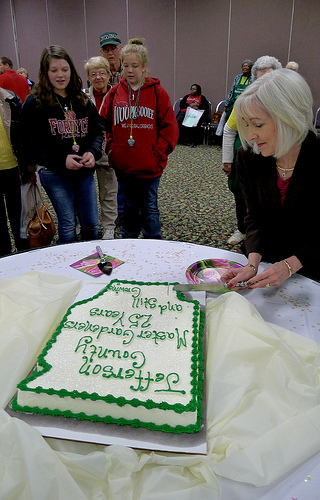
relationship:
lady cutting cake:
[217, 68, 319, 291] [6, 278, 204, 432]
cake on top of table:
[14, 275, 215, 445] [1, 227, 75, 305]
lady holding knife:
[217, 68, 319, 291] [171, 277, 258, 296]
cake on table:
[12, 278, 206, 435] [0, 231, 319, 498]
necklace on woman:
[275, 156, 298, 180] [224, 66, 318, 221]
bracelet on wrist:
[281, 259, 291, 276] [277, 251, 302, 282]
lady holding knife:
[217, 68, 319, 291] [174, 281, 247, 294]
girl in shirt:
[97, 35, 183, 241] [98, 77, 178, 179]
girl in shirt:
[19, 44, 107, 241] [10, 88, 104, 171]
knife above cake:
[169, 279, 230, 297] [57, 267, 236, 438]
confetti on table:
[124, 247, 185, 278] [12, 216, 319, 490]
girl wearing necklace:
[97, 38, 177, 241] [129, 84, 149, 107]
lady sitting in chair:
[174, 84, 211, 149] [199, 100, 210, 126]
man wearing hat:
[89, 27, 128, 62] [99, 29, 122, 45]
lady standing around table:
[217, 68, 319, 291] [0, 231, 319, 498]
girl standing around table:
[97, 38, 177, 241] [0, 231, 319, 498]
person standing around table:
[24, 43, 103, 244] [0, 231, 319, 498]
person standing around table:
[82, 55, 118, 238] [0, 231, 319, 498]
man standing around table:
[97, 27, 124, 85] [0, 231, 319, 498]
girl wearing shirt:
[97, 35, 183, 241] [98, 77, 178, 179]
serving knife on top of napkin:
[92, 243, 116, 278] [63, 249, 102, 278]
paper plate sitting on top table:
[184, 257, 251, 292] [17, 218, 310, 406]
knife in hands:
[169, 271, 227, 308] [186, 231, 302, 348]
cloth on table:
[122, 233, 187, 282] [0, 231, 319, 498]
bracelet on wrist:
[281, 259, 291, 276] [278, 255, 295, 277]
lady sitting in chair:
[174, 84, 211, 149] [172, 96, 212, 121]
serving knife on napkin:
[92, 243, 116, 278] [65, 250, 127, 279]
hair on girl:
[32, 43, 96, 112] [97, 35, 183, 241]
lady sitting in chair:
[174, 84, 211, 149] [169, 94, 230, 143]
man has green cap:
[97, 27, 124, 85] [95, 31, 121, 47]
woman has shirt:
[223, 53, 264, 149] [227, 70, 257, 116]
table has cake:
[0, 231, 319, 498] [12, 278, 206, 435]